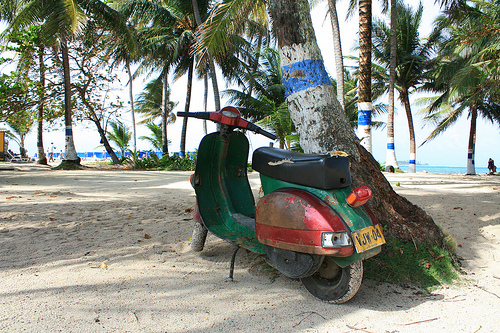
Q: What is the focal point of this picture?
A: A moped.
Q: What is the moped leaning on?
A: A tree.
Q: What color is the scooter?
A: Green and red.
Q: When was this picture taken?
A: Daytime.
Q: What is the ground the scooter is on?
A: Sand.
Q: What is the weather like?
A: Fair and sunny.